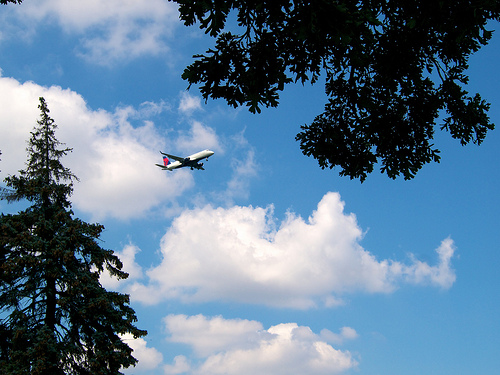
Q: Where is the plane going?
A: It is traveling to an airport.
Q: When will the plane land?
A: When it reaches an airport.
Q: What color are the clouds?
A: White.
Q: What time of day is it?
A: Daytime.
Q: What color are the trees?
A: Green.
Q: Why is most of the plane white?
A: Because the company that owns the plane chose that color.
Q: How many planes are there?
A: One.